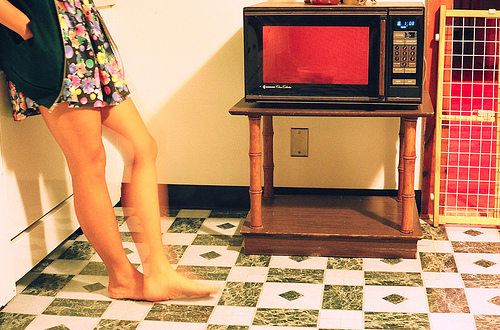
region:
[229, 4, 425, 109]
A dish is heating up in microwave.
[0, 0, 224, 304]
Person is leaning up against cabinet.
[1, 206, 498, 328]
The floor has checkered tile.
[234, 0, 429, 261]
Brown table with microwave sitting on top.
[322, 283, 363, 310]
Tile with green marble design.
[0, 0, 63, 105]
The jacket is green.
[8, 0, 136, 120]
Clothing has a floral pattern.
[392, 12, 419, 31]
1 minute is on the screen.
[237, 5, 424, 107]
Food is being microwaved.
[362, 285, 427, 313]
White tile with a green marbled square in the center.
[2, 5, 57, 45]
hand in the womans pocket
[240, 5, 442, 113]
microwave on a table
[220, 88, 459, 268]
table with microwave on it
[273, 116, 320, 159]
plug point behind the table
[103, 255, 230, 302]
barefeet crossed over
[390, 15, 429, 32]
the display of the microwave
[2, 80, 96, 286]
shadow of woman against the cupboard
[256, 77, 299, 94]
the name of the microwave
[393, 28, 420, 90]
touch panel of the microwave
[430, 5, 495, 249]
slatted gate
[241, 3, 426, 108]
the microwave on the stand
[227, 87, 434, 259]
the stand under the microwave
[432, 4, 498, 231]
the wooden baby gate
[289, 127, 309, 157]
the silver plate on the wall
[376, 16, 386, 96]
the door handle on the microwave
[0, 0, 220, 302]
the woman leaning on the counter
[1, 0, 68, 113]
the woman's hand in the pocket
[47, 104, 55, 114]
the zipper pull on the jacket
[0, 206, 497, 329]
the flooring in the kitchen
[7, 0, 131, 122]
the woman's floral skirt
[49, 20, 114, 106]
floral pattern on a dress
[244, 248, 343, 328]
geometric pattern on the floor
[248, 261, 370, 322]
checkered floor tiles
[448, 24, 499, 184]
baby gate in a door way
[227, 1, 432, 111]
microwave in a kitchen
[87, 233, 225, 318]
crossed bare feet on the floor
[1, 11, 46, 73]
hand in a black sweater pocket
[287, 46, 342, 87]
food inside of a microwave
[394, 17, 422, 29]
digital timer on a microwave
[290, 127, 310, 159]
silver electic socket on the wall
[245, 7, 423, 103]
this is a microwave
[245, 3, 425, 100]
the microwave is closed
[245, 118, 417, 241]
this is a stool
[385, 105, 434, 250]
the legs are wooden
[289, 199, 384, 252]
the stand is stable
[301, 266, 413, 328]
this is the floor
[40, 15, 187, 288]
this is a lady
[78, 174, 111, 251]
this is the leg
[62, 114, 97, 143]
the leg is white in color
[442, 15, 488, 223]
this is a grilled fence